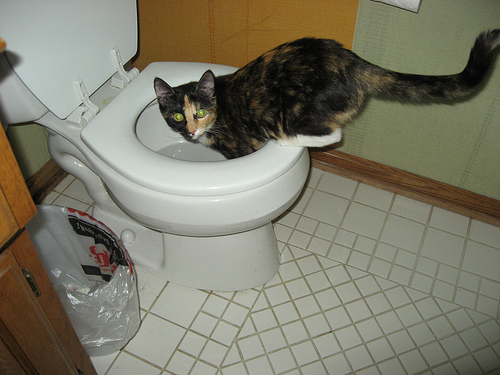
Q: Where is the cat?
A: IN the toilet.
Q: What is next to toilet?
A: Wastebasket.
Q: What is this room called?
A: A bathroom.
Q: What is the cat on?
A: A toilet.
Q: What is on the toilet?
A: Cat.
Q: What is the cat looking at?
A: The camera.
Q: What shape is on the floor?
A: Square.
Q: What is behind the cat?
A: A wall.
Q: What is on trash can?
A: A plastic bag.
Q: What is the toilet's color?
A: White.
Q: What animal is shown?
A: A cat.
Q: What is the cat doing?
A: Playing in the water.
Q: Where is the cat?
A: On the toilet.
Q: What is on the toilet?
A: The cat.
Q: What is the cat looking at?
A: The camera.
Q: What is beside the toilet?
A: The trashcan.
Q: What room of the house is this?
A: Bathroom.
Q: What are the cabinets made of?
A: Wood.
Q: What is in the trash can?
A: Plastic bag.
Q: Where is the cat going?
A: Into toilet.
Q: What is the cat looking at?
A: Camera.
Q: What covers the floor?
A: White tile.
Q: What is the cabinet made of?
A: Wood.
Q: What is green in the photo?
A: Cat's eyes.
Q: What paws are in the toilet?
A: Front paws.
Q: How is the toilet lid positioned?
A: Up.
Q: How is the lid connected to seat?
A: Hinges.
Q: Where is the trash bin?
A: On floor.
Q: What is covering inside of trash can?
A: Plastic bag.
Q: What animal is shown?
A: Cat.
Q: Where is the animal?
A: On the toilet.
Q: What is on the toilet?
A: A cat.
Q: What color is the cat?
A: Brown.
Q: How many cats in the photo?
A: One.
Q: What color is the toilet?
A: White.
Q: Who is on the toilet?
A: A cat.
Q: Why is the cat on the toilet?
A: To drink water.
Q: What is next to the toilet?
A: A garbage.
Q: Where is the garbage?
A: Left side.